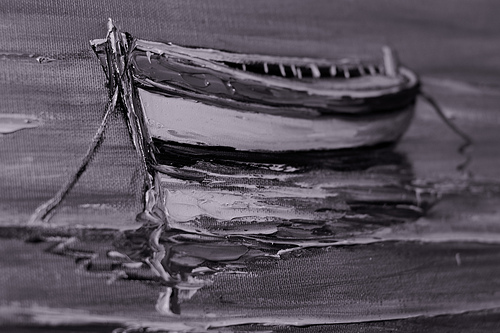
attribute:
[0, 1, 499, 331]
water — disturbed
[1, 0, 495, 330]
boat painting — black, white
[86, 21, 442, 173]
boat — black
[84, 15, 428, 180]
boat — wooden, empty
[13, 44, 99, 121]
grey paint — grey colored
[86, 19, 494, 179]
boat — small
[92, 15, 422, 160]
boat — wooden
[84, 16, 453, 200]
boat — docked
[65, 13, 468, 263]
boat — colorless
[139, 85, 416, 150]
stripe — white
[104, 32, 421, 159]
boat — pastel painted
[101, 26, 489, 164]
boat — white, grey, black, striped